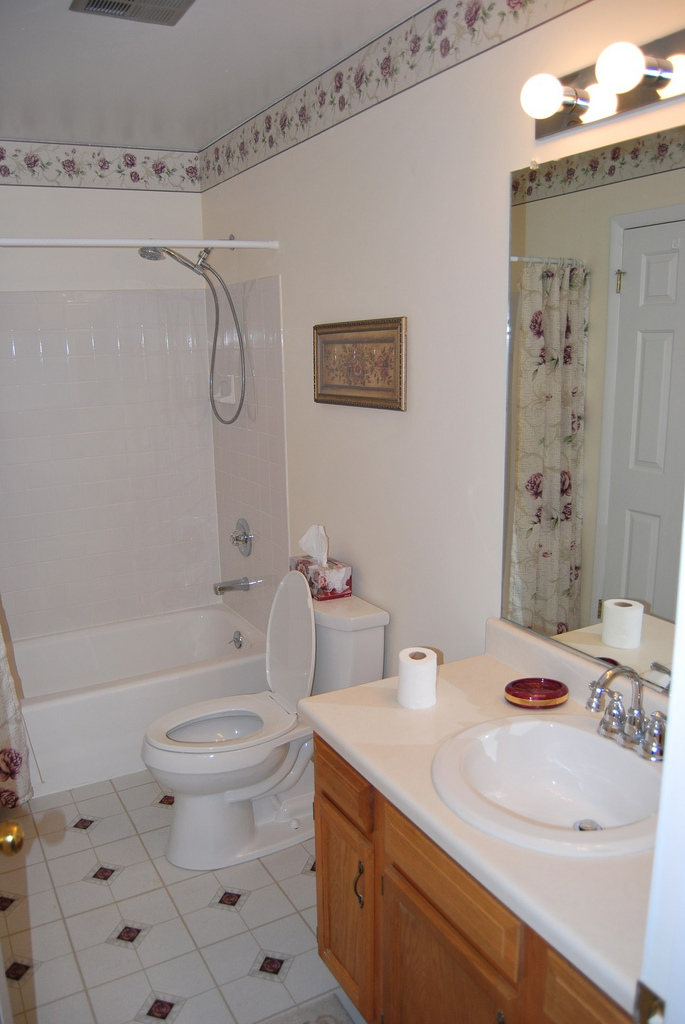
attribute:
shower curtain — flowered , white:
[531, 266, 567, 546]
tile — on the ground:
[77, 871, 190, 991]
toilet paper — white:
[390, 643, 442, 712]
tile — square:
[111, 877, 185, 939]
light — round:
[589, 41, 650, 99]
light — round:
[522, 71, 569, 120]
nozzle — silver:
[140, 243, 171, 261]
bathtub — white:
[6, 604, 266, 807]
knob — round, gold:
[0, 813, 23, 859]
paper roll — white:
[393, 645, 440, 712]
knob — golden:
[0, 815, 36, 862]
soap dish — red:
[500, 668, 577, 716]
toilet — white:
[143, 569, 390, 872]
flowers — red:
[292, 560, 353, 601]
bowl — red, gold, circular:
[503, 677, 572, 711]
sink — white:
[432, 712, 663, 856]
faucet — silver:
[585, 663, 647, 750]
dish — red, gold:
[500, 675, 570, 709]